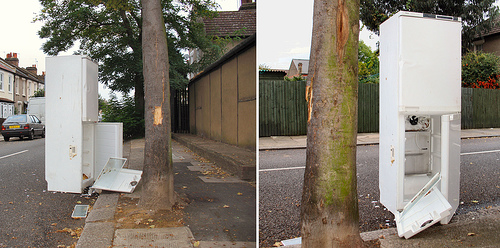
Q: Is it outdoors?
A: Yes, it is outdoors.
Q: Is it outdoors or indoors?
A: It is outdoors.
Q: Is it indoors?
A: No, it is outdoors.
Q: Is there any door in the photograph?
A: Yes, there is a door.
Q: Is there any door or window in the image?
A: Yes, there is a door.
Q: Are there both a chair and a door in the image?
A: No, there is a door but no chairs.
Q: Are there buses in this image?
A: No, there are no buses.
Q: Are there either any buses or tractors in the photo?
A: No, there are no buses or tractors.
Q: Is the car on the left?
A: Yes, the car is on the left of the image.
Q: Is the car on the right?
A: No, the car is on the left of the image.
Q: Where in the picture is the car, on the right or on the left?
A: The car is on the left of the image.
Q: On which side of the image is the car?
A: The car is on the left of the image.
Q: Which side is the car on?
A: The car is on the left of the image.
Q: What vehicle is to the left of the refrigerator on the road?
A: The vehicle is a car.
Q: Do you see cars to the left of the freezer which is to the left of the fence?
A: Yes, there is a car to the left of the refrigerator.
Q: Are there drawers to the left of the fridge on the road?
A: No, there is a car to the left of the fridge.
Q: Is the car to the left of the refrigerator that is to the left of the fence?
A: Yes, the car is to the left of the freezer.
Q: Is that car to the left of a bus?
A: No, the car is to the left of the freezer.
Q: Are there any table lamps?
A: No, there are no table lamps.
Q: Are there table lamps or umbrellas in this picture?
A: No, there are no table lamps or umbrellas.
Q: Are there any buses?
A: No, there are no buses.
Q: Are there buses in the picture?
A: No, there are no buses.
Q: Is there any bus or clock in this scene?
A: No, there are no buses or clocks.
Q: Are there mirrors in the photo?
A: No, there are no mirrors.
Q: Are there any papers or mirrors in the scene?
A: No, there are no mirrors or papers.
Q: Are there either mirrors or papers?
A: No, there are no mirrors or papers.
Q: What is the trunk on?
A: The trunk is on the tree.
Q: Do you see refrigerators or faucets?
A: Yes, there is a refrigerator.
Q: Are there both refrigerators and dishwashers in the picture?
A: No, there is a refrigerator but no dishwashers.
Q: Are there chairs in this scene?
A: No, there are no chairs.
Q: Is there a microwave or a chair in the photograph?
A: No, there are no chairs or microwaves.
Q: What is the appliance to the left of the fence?
A: The appliance is a refrigerator.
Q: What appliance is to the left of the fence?
A: The appliance is a refrigerator.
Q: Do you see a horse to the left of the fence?
A: No, there is a refrigerator to the left of the fence.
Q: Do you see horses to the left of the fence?
A: No, there is a refrigerator to the left of the fence.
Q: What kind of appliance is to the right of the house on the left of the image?
A: The appliance is a refrigerator.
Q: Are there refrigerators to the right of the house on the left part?
A: Yes, there is a refrigerator to the right of the house.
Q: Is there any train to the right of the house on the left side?
A: No, there is a refrigerator to the right of the house.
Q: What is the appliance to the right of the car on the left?
A: The appliance is a refrigerator.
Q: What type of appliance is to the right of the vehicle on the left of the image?
A: The appliance is a refrigerator.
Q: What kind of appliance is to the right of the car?
A: The appliance is a refrigerator.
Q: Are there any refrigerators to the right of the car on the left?
A: Yes, there is a refrigerator to the right of the car.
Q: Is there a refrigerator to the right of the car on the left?
A: Yes, there is a refrigerator to the right of the car.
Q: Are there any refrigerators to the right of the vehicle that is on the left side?
A: Yes, there is a refrigerator to the right of the car.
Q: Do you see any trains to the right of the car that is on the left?
A: No, there is a refrigerator to the right of the car.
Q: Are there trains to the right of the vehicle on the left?
A: No, there is a refrigerator to the right of the car.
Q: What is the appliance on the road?
A: The appliance is a refrigerator.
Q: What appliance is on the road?
A: The appliance is a refrigerator.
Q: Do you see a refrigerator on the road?
A: Yes, there is a refrigerator on the road.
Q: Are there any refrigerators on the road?
A: Yes, there is a refrigerator on the road.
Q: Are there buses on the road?
A: No, there is a refrigerator on the road.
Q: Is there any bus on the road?
A: No, there is a refrigerator on the road.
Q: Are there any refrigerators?
A: Yes, there is a refrigerator.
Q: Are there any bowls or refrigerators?
A: Yes, there is a refrigerator.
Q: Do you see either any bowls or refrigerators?
A: Yes, there is a refrigerator.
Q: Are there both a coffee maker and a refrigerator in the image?
A: No, there is a refrigerator but no coffee makers.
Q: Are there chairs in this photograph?
A: No, there are no chairs.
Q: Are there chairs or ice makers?
A: No, there are no chairs or ice makers.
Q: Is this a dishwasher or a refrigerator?
A: This is a refrigerator.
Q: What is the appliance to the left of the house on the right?
A: The appliance is a refrigerator.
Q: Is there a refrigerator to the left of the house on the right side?
A: Yes, there is a refrigerator to the left of the house.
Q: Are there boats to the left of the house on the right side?
A: No, there is a refrigerator to the left of the house.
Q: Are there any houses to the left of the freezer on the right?
A: Yes, there is a house to the left of the refrigerator.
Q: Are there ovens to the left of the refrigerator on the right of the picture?
A: No, there is a house to the left of the refrigerator.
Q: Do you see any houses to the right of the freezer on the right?
A: Yes, there is a house to the right of the freezer.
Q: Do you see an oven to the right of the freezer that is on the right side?
A: No, there is a house to the right of the freezer.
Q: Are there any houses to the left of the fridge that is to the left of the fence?
A: Yes, there is a house to the left of the fridge.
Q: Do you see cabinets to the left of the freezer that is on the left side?
A: No, there is a house to the left of the refrigerator.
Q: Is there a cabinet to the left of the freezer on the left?
A: No, there is a house to the left of the refrigerator.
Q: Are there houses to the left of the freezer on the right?
A: Yes, there is a house to the left of the fridge.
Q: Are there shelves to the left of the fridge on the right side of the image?
A: No, there is a house to the left of the refrigerator.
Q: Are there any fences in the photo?
A: Yes, there is a fence.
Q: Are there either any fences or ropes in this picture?
A: Yes, there is a fence.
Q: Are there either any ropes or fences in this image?
A: Yes, there is a fence.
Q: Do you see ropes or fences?
A: Yes, there is a fence.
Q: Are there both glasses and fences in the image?
A: No, there is a fence but no glasses.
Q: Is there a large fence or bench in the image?
A: Yes, there is a large fence.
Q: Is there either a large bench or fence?
A: Yes, there is a large fence.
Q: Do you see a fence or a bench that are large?
A: Yes, the fence is large.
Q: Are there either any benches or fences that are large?
A: Yes, the fence is large.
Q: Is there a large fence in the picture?
A: Yes, there is a large fence.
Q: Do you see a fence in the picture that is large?
A: Yes, there is a fence that is large.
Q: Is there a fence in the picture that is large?
A: Yes, there is a fence that is large.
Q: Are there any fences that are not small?
A: Yes, there is a large fence.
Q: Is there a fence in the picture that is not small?
A: Yes, there is a large fence.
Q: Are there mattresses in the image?
A: No, there are no mattresses.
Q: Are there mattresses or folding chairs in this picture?
A: No, there are no mattresses or folding chairs.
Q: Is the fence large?
A: Yes, the fence is large.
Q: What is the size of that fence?
A: The fence is large.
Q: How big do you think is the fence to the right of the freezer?
A: The fence is large.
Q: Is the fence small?
A: No, the fence is large.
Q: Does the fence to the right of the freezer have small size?
A: No, the fence is large.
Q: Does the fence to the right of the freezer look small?
A: No, the fence is large.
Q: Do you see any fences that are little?
A: No, there is a fence but it is large.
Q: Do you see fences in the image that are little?
A: No, there is a fence but it is large.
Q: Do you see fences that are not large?
A: No, there is a fence but it is large.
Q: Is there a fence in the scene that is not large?
A: No, there is a fence but it is large.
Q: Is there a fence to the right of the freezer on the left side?
A: Yes, there is a fence to the right of the fridge.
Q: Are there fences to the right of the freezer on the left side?
A: Yes, there is a fence to the right of the fridge.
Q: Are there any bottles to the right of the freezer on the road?
A: No, there is a fence to the right of the refrigerator.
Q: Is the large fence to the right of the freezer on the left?
A: Yes, the fence is to the right of the refrigerator.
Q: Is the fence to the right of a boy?
A: No, the fence is to the right of the refrigerator.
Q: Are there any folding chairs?
A: No, there are no folding chairs.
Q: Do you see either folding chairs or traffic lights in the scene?
A: No, there are no folding chairs or traffic lights.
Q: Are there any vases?
A: No, there are no vases.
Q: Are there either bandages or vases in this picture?
A: No, there are no vases or bandages.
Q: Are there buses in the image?
A: No, there are no buses.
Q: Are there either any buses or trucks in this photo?
A: No, there are no buses or trucks.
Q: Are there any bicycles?
A: No, there are no bicycles.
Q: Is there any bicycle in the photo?
A: No, there are no bicycles.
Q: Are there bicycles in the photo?
A: No, there are no bicycles.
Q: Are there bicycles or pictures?
A: No, there are no bicycles or pictures.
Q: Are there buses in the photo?
A: No, there are no buses.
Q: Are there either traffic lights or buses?
A: No, there are no buses or traffic lights.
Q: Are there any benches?
A: No, there are no benches.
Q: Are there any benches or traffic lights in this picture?
A: No, there are no benches or traffic lights.